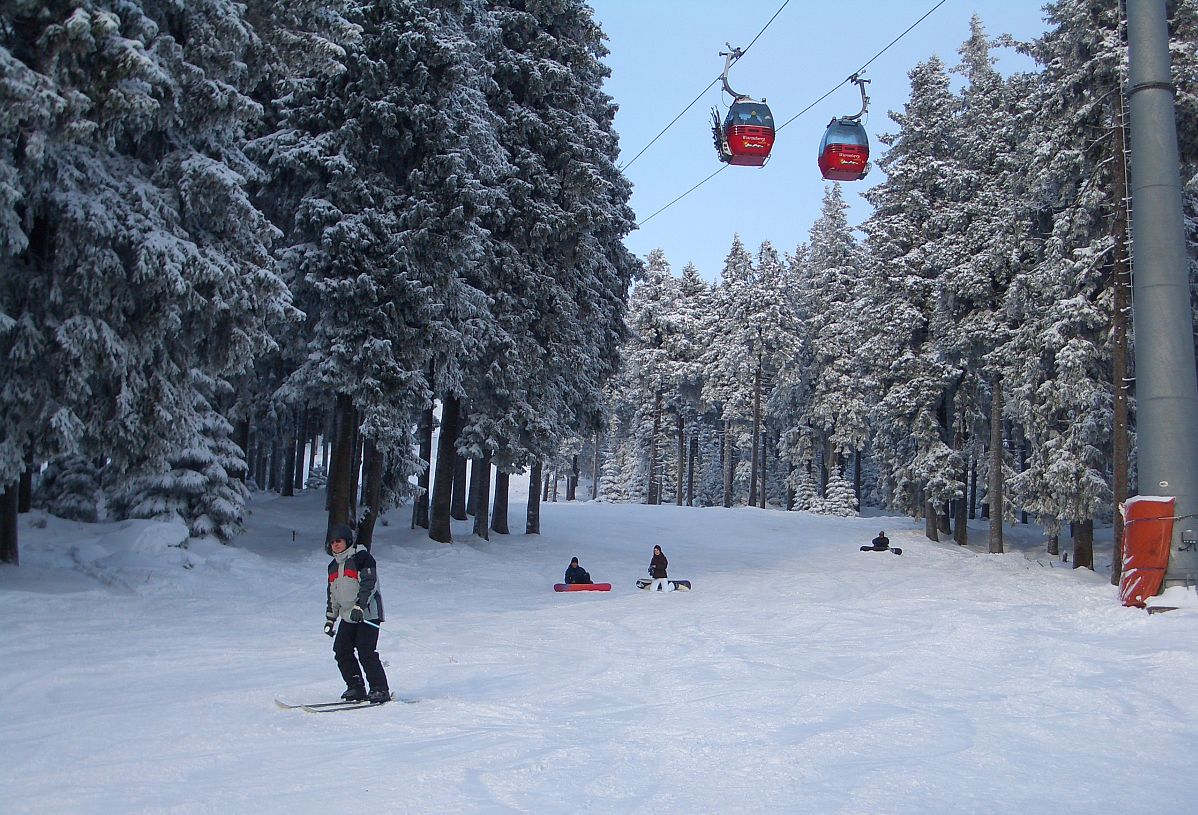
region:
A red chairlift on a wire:
[706, 37, 784, 172]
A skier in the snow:
[273, 522, 404, 718]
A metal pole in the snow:
[1118, 0, 1195, 592]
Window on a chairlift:
[733, 97, 772, 127]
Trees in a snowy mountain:
[829, 3, 1137, 555]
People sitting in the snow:
[535, 539, 695, 597]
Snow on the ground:
[14, 481, 1194, 807]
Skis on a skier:
[278, 679, 406, 716]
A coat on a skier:
[324, 542, 387, 641]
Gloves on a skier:
[340, 587, 379, 628]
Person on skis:
[268, 684, 410, 719]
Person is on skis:
[263, 677, 410, 721]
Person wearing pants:
[328, 609, 387, 699]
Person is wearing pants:
[323, 609, 405, 687]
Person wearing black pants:
[325, 607, 403, 701]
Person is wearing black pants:
[326, 614, 389, 694]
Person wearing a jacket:
[321, 549, 386, 634]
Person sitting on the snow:
[540, 542, 617, 600]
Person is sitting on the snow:
[542, 540, 617, 598]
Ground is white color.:
[114, 497, 1108, 760]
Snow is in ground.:
[118, 463, 960, 762]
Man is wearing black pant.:
[296, 510, 434, 734]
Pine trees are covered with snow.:
[68, 49, 1134, 478]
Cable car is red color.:
[645, 39, 882, 216]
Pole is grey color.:
[1098, 13, 1192, 581]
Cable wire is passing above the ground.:
[624, 8, 937, 239]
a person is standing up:
[304, 508, 399, 716]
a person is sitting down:
[562, 546, 606, 592]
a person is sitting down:
[637, 534, 688, 583]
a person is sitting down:
[862, 513, 897, 562]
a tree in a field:
[1007, 15, 1145, 560]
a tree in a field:
[928, 8, 1044, 535]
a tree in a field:
[824, 44, 972, 497]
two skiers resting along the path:
[551, 542, 698, 598]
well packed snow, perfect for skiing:
[5, 489, 1196, 812]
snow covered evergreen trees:
[2, 10, 1128, 579]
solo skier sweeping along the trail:
[281, 520, 409, 720]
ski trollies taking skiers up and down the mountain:
[714, 32, 874, 182]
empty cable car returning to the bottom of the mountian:
[818, 70, 874, 186]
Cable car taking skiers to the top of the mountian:
[710, 36, 780, 164]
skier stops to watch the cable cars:
[856, 525, 912, 555]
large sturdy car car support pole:
[1123, 0, 1194, 595]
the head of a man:
[308, 511, 371, 570]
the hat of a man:
[318, 521, 343, 539]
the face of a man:
[314, 526, 353, 565]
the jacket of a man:
[302, 547, 411, 632]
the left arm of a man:
[338, 552, 396, 637]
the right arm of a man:
[304, 576, 369, 673]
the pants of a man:
[318, 624, 406, 709]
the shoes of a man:
[335, 670, 405, 709]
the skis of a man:
[246, 678, 391, 720]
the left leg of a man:
[340, 627, 405, 690]